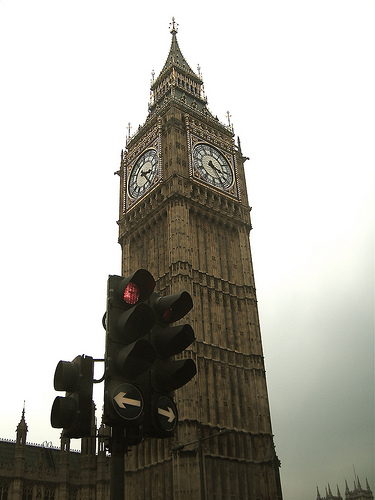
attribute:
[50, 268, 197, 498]
signallight — signal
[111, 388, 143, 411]
arrow — white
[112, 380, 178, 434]
sign — black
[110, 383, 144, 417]
circle — black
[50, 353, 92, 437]
traffic light — black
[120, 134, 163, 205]
clock — face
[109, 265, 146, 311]
light — metal, traffic light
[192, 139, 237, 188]
clocks — circular, analog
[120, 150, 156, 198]
clocks — circular, analog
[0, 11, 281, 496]
tower — stone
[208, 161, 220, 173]
hands — black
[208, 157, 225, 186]
hands — black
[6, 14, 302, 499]
building — large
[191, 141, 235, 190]
clock — face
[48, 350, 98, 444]
traffic light — small, black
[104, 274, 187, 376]
light — red, traffic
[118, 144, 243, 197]
clocks — large, analog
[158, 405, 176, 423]
arrow — white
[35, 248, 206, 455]
traffic light — black